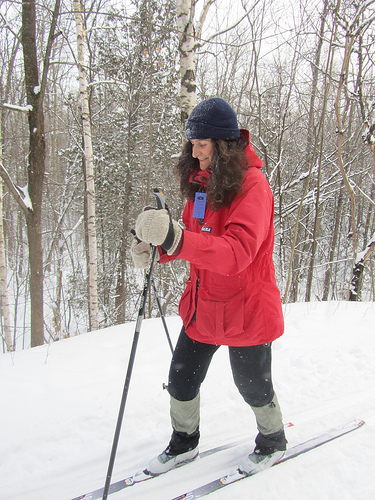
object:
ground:
[0, 340, 375, 500]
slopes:
[0, 354, 363, 488]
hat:
[182, 97, 241, 140]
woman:
[128, 94, 290, 484]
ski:
[68, 417, 211, 498]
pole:
[148, 276, 176, 348]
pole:
[98, 243, 157, 499]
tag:
[192, 192, 208, 218]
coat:
[167, 129, 284, 345]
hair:
[205, 133, 248, 207]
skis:
[63, 422, 369, 500]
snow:
[3, 300, 372, 494]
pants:
[165, 323, 285, 454]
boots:
[143, 429, 200, 477]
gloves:
[135, 206, 183, 257]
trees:
[1, 0, 67, 340]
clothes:
[170, 150, 285, 441]